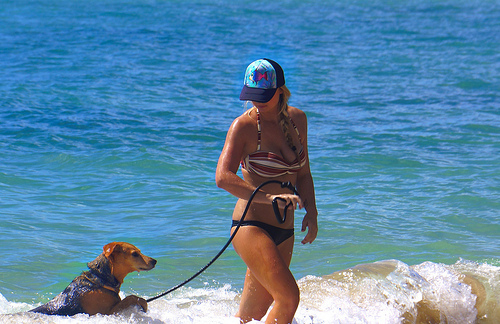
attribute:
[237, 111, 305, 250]
suit — bathing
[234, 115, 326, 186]
top — red, white, striped, bikini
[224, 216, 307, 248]
bottom — bikini, black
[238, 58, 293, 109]
hat — blue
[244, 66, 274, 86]
fish — pink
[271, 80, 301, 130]
hair — woman's, blonde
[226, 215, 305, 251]
bottom — black, bathing suit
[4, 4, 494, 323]
body — blue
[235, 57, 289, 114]
cap — trucker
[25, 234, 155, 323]
dog — brown, tan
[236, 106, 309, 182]
top — swim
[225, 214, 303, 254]
bottom — swim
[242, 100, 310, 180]
top — striped, swim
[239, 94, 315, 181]
top — swim